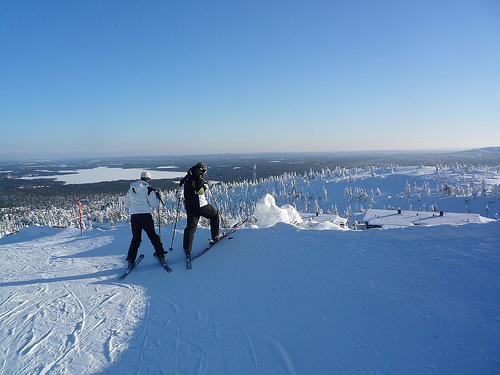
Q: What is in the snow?
A: Tracks.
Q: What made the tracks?
A: Skis.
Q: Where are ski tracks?
A: On the snow.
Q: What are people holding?
A: Ski poles.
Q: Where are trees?
A: In the distance.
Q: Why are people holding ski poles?
A: To ski.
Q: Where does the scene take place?
A: On a ski slope.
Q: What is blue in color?
A: The sky.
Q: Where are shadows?
A: On the snow.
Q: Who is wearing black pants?
A: Two skiers.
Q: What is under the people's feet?
A: Skis.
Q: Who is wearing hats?
A: The skiers.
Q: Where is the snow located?
A: On a mountain.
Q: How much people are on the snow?
A: Two.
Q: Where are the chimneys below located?
A: On a roof.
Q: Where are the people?
A: On a mountain.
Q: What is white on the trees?
A: Snow.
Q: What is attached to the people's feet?
A: Skis.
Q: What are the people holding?
A: Ski poles.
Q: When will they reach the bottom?
A: When they go down the hill.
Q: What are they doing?
A: Skiing.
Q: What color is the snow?
A: White.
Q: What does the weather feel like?
A: Cold.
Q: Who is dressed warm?
A: The people.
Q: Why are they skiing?
A: For fun.